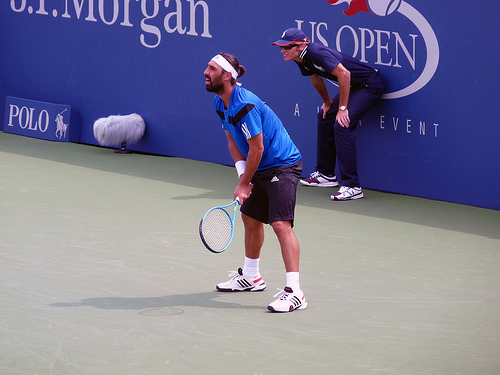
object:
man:
[197, 50, 309, 313]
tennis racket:
[197, 183, 251, 253]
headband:
[209, 53, 242, 88]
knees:
[268, 214, 290, 233]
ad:
[2, 93, 72, 143]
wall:
[0, 0, 499, 211]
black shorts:
[237, 157, 307, 229]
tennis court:
[0, 134, 499, 375]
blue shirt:
[292, 42, 382, 89]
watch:
[336, 105, 349, 112]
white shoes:
[265, 283, 310, 313]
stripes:
[286, 294, 302, 308]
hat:
[271, 29, 312, 47]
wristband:
[233, 160, 248, 180]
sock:
[241, 254, 263, 276]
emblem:
[267, 174, 282, 184]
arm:
[233, 109, 264, 188]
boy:
[271, 28, 384, 201]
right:
[215, 266, 267, 291]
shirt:
[210, 84, 302, 172]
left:
[264, 286, 309, 314]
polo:
[6, 103, 51, 135]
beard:
[204, 82, 227, 94]